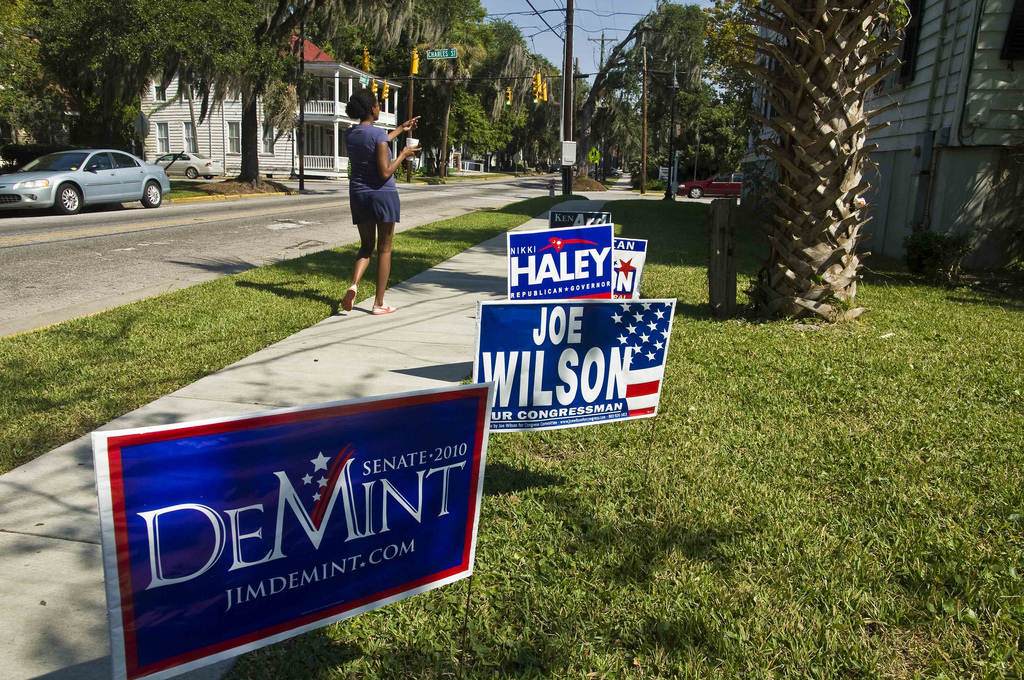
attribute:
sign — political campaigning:
[474, 281, 675, 433]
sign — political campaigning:
[499, 218, 620, 307]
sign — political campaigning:
[598, 235, 653, 297]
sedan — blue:
[0, 146, 174, 224]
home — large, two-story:
[151, 26, 415, 208]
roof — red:
[282, 29, 340, 64]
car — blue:
[5, 138, 162, 212]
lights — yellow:
[332, 45, 560, 123]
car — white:
[159, 143, 217, 169]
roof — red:
[282, 39, 352, 62]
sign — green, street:
[408, 40, 462, 59]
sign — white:
[98, 387, 487, 660]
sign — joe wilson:
[473, 292, 669, 435]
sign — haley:
[507, 223, 621, 293]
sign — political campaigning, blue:
[87, 377, 490, 672]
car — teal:
[5, 137, 167, 205]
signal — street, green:
[494, 80, 514, 109]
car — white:
[117, 135, 257, 186]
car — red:
[702, 164, 786, 204]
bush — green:
[893, 211, 1021, 313]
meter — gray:
[903, 132, 984, 266]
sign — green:
[427, 38, 467, 67]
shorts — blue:
[331, 181, 418, 214]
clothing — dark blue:
[344, 126, 405, 228]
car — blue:
[1, 136, 172, 217]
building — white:
[137, 21, 401, 190]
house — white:
[118, 17, 408, 203]